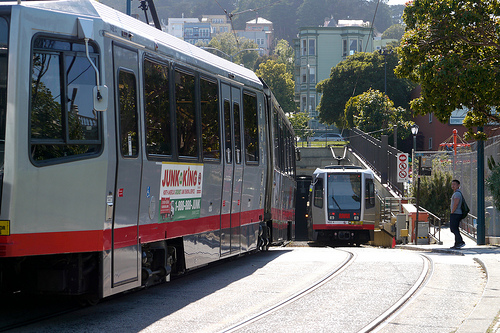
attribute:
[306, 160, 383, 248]
train — silver, white, red, riding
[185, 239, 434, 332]
tracks — train, railway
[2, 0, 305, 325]
train — silver, white, red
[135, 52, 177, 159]
windows — passenger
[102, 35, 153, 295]
door — entrance, exit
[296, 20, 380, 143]
buildings — background, light yellow, tall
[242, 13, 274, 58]
buildings — background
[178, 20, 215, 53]
buildings — background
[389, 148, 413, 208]
signs — traffic, directional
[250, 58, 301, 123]
trees — background, tall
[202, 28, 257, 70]
trees — background, tall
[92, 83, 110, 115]
mirror — sideview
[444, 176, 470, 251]
man — standing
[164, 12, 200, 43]
buildings — white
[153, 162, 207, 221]
advertisement — promotional, banner, red, white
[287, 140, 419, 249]
tunnel — train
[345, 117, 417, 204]
fence — black, metal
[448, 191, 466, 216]
shirt — gray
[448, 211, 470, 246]
pants — black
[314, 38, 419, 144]
tree — tall, bushy